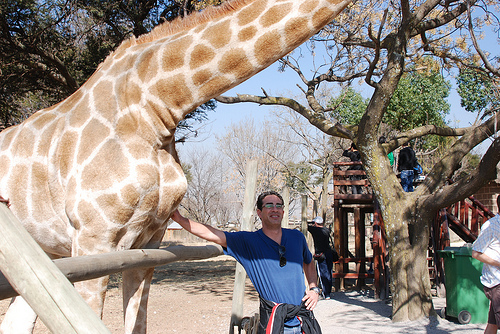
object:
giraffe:
[0, 0, 355, 334]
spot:
[216, 48, 256, 83]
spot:
[199, 18, 233, 49]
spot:
[145, 73, 193, 113]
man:
[170, 189, 322, 333]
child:
[339, 142, 365, 192]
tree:
[211, 1, 500, 325]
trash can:
[436, 247, 489, 326]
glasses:
[259, 201, 283, 209]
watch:
[309, 287, 319, 292]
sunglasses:
[276, 241, 289, 268]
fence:
[1, 159, 333, 332]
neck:
[89, 0, 352, 126]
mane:
[96, 3, 259, 70]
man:
[466, 196, 499, 334]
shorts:
[480, 284, 499, 328]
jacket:
[222, 228, 312, 327]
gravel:
[1, 259, 317, 333]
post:
[367, 209, 389, 301]